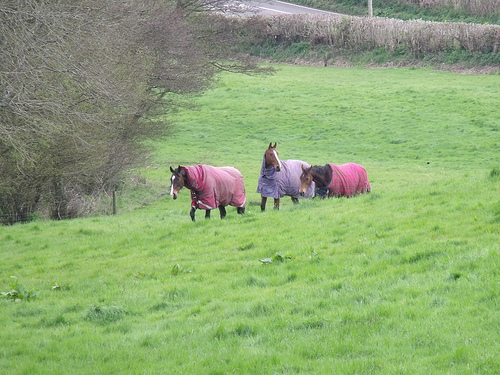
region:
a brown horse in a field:
[162, 160, 244, 220]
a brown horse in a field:
[258, 141, 312, 211]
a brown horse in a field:
[297, 161, 371, 203]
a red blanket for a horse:
[184, 165, 243, 210]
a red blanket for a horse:
[325, 161, 369, 201]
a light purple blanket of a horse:
[257, 159, 312, 199]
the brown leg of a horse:
[187, 203, 197, 222]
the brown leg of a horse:
[202, 203, 211, 222]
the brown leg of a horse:
[218, 202, 227, 218]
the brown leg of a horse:
[235, 202, 246, 214]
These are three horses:
[108, 132, 393, 265]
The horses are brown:
[166, 162, 416, 270]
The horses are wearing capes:
[168, 158, 377, 241]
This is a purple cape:
[260, 187, 297, 189]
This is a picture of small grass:
[141, 235, 320, 339]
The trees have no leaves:
[51, 69, 118, 176]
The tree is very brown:
[63, 57, 143, 152]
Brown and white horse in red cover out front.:
[166, 163, 246, 217]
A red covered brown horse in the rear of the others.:
[297, 163, 369, 196]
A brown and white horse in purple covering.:
[258, 141, 316, 209]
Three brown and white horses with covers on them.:
[171, 138, 370, 220]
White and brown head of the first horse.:
[167, 164, 185, 202]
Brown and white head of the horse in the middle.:
[266, 143, 283, 173]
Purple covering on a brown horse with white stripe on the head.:
[255, 150, 314, 195]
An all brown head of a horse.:
[298, 165, 314, 197]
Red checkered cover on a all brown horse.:
[322, 163, 368, 200]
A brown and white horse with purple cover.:
[257, 143, 315, 211]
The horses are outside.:
[3, 0, 495, 371]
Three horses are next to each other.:
[166, 140, 372, 226]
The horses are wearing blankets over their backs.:
[165, 140, 371, 225]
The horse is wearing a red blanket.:
[182, 165, 243, 206]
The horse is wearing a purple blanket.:
[255, 155, 306, 201]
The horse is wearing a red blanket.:
[325, 161, 367, 197]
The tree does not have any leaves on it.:
[0, 0, 251, 215]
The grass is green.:
[0, 240, 495, 370]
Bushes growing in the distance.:
[215, 12, 495, 59]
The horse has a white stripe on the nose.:
[168, 173, 177, 199]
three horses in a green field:
[91, 65, 480, 340]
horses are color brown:
[144, 128, 381, 222]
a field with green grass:
[46, 65, 488, 366]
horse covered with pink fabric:
[293, 156, 380, 206]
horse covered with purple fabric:
[245, 135, 320, 214]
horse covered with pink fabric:
[159, 153, 257, 228]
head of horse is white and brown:
[161, 160, 186, 201]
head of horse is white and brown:
[255, 132, 290, 173]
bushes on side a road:
[222, 0, 499, 79]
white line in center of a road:
[233, 0, 310, 23]